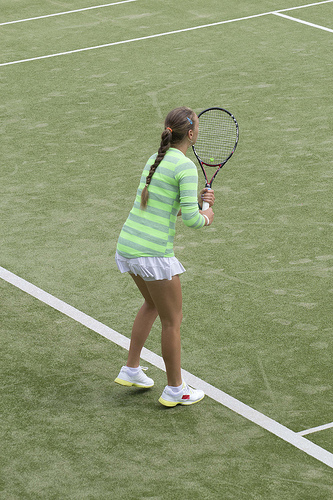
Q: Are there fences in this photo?
A: No, there are no fences.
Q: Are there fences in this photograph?
A: No, there are no fences.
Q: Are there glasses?
A: No, there are no glasses.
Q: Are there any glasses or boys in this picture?
A: No, there are no glasses or boys.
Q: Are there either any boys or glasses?
A: No, there are no glasses or boys.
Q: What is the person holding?
A: The player is holding the racket.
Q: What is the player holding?
A: The player is holding the racket.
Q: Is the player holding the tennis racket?
A: Yes, the player is holding the tennis racket.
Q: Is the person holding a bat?
A: No, the player is holding the tennis racket.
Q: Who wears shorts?
A: The player wears shorts.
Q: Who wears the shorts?
A: The player wears shorts.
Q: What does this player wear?
A: The player wears shorts.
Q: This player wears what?
A: The player wears shorts.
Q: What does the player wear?
A: The player wears shorts.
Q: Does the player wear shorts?
A: Yes, the player wears shorts.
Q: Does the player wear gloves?
A: No, the player wears shorts.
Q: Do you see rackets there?
A: Yes, there is a racket.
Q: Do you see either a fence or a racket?
A: Yes, there is a racket.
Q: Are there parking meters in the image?
A: No, there are no parking meters.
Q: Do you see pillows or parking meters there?
A: No, there are no parking meters or pillows.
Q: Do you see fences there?
A: No, there are no fences.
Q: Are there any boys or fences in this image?
A: No, there are no fences or boys.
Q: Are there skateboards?
A: No, there are no skateboards.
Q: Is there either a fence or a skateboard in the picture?
A: No, there are no skateboards or fences.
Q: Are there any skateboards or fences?
A: No, there are no skateboards or fences.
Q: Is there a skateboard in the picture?
A: No, there are no skateboards.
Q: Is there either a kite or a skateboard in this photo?
A: No, there are no skateboards or kites.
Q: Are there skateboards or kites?
A: No, there are no skateboards or kites.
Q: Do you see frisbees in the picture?
A: No, there are no frisbees.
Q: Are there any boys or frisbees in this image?
A: No, there are no frisbees or boys.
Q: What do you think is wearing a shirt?
A: The shorts are wearing a shirt.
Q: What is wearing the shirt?
A: The shorts are wearing a shirt.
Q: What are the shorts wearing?
A: The shorts are wearing a shirt.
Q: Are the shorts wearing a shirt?
A: Yes, the shorts are wearing a shirt.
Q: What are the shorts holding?
A: The shorts are holding the tennis racket.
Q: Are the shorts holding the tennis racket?
A: Yes, the shorts are holding the tennis racket.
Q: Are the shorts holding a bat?
A: No, the shorts are holding the tennis racket.